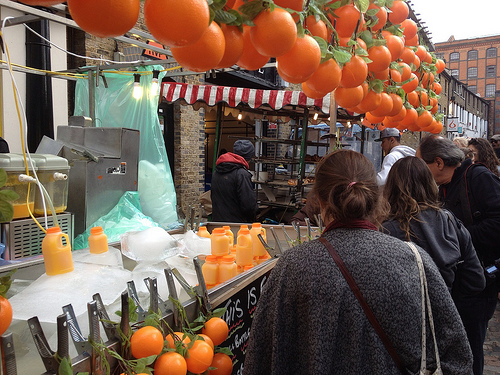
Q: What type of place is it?
A: It is a shopping center.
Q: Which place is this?
A: It is a shopping center.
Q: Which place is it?
A: It is a shopping center.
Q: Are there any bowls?
A: No, there are no bowls.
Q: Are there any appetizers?
A: No, there are no appetizers.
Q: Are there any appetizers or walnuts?
A: No, there are no appetizers or walnuts.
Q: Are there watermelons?
A: No, there are no watermelons.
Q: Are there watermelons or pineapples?
A: No, there are no watermelons or pineapples.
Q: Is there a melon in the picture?
A: No, there are no melons.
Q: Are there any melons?
A: No, there are no melons.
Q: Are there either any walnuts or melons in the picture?
A: No, there are no melons or walnuts.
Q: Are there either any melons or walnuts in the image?
A: No, there are no melons or walnuts.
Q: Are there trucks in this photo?
A: Yes, there is a truck.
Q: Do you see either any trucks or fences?
A: Yes, there is a truck.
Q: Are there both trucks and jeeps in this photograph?
A: No, there is a truck but no jeeps.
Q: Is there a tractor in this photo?
A: No, there are no tractors.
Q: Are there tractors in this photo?
A: No, there are no tractors.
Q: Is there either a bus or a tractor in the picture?
A: No, there are no tractors or buses.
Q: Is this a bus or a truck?
A: This is a truck.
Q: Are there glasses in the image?
A: No, there are no glasses.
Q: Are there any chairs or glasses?
A: No, there are no glasses or chairs.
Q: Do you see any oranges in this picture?
A: Yes, there are oranges.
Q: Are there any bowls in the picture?
A: No, there are no bowls.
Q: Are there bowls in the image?
A: No, there are no bowls.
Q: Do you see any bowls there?
A: No, there are no bowls.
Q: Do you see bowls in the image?
A: No, there are no bowls.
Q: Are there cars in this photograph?
A: No, there are no cars.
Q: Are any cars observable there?
A: No, there are no cars.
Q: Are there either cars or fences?
A: No, there are no cars or fences.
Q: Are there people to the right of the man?
A: Yes, there are people to the right of the man.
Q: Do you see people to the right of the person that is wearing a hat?
A: Yes, there are people to the right of the man.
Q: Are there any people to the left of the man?
A: No, the people are to the right of the man.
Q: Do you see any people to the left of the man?
A: No, the people are to the right of the man.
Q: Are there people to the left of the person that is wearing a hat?
A: No, the people are to the right of the man.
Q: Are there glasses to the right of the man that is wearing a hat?
A: No, there are people to the right of the man.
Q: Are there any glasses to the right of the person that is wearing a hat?
A: No, there are people to the right of the man.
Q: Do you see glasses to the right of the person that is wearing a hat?
A: No, there are people to the right of the man.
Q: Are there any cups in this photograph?
A: No, there are no cups.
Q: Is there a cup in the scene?
A: No, there are no cups.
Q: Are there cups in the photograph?
A: No, there are no cups.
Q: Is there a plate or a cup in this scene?
A: No, there are no cups or plates.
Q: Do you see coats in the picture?
A: Yes, there is a coat.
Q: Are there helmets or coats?
A: Yes, there is a coat.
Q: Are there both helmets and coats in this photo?
A: No, there is a coat but no helmets.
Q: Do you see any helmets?
A: No, there are no helmets.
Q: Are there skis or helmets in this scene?
A: No, there are no helmets or skis.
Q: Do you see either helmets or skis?
A: No, there are no helmets or skis.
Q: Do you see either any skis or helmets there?
A: No, there are no helmets or skis.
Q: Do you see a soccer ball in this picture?
A: No, there are no soccer balls.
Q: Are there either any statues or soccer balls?
A: No, there are no soccer balls or statues.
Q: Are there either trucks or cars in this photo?
A: Yes, there is a truck.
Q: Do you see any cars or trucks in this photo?
A: Yes, there is a truck.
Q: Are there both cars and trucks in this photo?
A: No, there is a truck but no cars.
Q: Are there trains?
A: No, there are no trains.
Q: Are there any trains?
A: No, there are no trains.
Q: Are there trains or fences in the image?
A: No, there are no trains or fences.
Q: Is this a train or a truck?
A: This is a truck.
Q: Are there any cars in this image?
A: No, there are no cars.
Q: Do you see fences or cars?
A: No, there are no cars or fences.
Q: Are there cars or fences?
A: No, there are no cars or fences.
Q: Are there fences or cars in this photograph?
A: No, there are no cars or fences.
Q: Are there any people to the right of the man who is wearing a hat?
A: Yes, there are people to the right of the man.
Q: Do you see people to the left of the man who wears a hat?
A: No, the people are to the right of the man.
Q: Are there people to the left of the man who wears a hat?
A: No, the people are to the right of the man.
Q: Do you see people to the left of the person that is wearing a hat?
A: No, the people are to the right of the man.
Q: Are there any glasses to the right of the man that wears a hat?
A: No, there are people to the right of the man.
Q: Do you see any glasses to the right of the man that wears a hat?
A: No, there are people to the right of the man.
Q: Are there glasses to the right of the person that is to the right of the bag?
A: No, there are people to the right of the man.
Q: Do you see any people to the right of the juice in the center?
A: Yes, there are people to the right of the juice.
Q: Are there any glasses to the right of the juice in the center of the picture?
A: No, there are people to the right of the juice.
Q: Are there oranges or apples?
A: Yes, there are oranges.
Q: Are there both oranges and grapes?
A: No, there are oranges but no grapes.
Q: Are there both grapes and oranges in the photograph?
A: No, there are oranges but no grapes.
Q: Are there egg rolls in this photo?
A: No, there are no egg rolls.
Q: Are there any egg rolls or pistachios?
A: No, there are no egg rolls or pistachios.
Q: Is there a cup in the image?
A: No, there are no cups.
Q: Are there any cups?
A: No, there are no cups.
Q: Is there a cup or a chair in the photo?
A: No, there are no cups or chairs.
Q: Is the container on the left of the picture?
A: Yes, the container is on the left of the image.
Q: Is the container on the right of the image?
A: No, the container is on the left of the image.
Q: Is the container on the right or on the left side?
A: The container is on the left of the image.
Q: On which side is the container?
A: The container is on the left of the image.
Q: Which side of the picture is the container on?
A: The container is on the left of the image.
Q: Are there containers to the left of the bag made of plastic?
A: Yes, there is a container to the left of the bag.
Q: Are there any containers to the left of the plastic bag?
A: Yes, there is a container to the left of the bag.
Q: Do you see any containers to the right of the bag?
A: No, the container is to the left of the bag.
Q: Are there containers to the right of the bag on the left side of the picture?
A: No, the container is to the left of the bag.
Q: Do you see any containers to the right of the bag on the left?
A: No, the container is to the left of the bag.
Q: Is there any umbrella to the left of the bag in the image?
A: No, there is a container to the left of the bag.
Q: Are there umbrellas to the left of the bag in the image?
A: No, there is a container to the left of the bag.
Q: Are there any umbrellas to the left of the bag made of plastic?
A: No, there is a container to the left of the bag.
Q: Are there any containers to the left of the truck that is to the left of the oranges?
A: Yes, there is a container to the left of the truck.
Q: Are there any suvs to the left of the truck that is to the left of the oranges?
A: No, there is a container to the left of the truck.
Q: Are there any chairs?
A: No, there are no chairs.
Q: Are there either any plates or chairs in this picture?
A: No, there are no chairs or plates.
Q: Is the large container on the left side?
A: Yes, the container is on the left of the image.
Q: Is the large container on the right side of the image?
A: No, the container is on the left of the image.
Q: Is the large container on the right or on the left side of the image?
A: The container is on the left of the image.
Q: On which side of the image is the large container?
A: The container is on the left of the image.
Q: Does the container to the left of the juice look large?
A: Yes, the container is large.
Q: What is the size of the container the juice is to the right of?
A: The container is large.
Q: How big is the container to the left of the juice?
A: The container is large.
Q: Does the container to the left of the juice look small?
A: No, the container is large.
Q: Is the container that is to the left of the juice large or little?
A: The container is large.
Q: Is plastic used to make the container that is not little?
A: Yes, the container is made of plastic.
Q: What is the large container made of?
A: The container is made of plastic.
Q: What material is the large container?
A: The container is made of plastic.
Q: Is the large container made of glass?
A: No, the container is made of plastic.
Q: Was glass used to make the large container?
A: No, the container is made of plastic.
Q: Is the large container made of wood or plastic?
A: The container is made of plastic.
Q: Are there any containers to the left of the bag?
A: Yes, there is a container to the left of the bag.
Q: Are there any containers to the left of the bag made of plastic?
A: Yes, there is a container to the left of the bag.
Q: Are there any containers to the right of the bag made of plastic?
A: No, the container is to the left of the bag.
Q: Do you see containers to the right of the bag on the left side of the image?
A: No, the container is to the left of the bag.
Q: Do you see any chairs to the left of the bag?
A: No, there is a container to the left of the bag.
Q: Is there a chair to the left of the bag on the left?
A: No, there is a container to the left of the bag.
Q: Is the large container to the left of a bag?
A: Yes, the container is to the left of a bag.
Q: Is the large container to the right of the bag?
A: No, the container is to the left of the bag.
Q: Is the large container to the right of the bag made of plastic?
A: No, the container is to the left of the bag.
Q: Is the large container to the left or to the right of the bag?
A: The container is to the left of the bag.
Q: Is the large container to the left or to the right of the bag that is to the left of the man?
A: The container is to the left of the bag.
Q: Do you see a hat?
A: Yes, there is a hat.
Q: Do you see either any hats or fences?
A: Yes, there is a hat.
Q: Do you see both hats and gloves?
A: No, there is a hat but no gloves.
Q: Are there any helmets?
A: No, there are no helmets.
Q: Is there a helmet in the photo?
A: No, there are no helmets.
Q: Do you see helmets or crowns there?
A: No, there are no helmets or crowns.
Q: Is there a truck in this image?
A: Yes, there is a truck.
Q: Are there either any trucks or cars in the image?
A: Yes, there is a truck.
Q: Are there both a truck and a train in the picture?
A: No, there is a truck but no trains.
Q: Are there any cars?
A: No, there are no cars.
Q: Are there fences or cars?
A: No, there are no cars or fences.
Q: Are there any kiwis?
A: No, there are no kiwis.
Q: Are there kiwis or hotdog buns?
A: No, there are no kiwis or hotdog buns.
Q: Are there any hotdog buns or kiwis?
A: No, there are no kiwis or hotdog buns.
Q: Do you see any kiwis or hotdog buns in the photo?
A: No, there are no kiwis or hotdog buns.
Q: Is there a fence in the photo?
A: No, there are no fences.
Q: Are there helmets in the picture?
A: No, there are no helmets.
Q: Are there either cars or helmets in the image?
A: No, there are no helmets or cars.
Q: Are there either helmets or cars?
A: No, there are no helmets or cars.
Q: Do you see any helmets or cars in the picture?
A: No, there are no helmets or cars.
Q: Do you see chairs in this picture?
A: No, there are no chairs.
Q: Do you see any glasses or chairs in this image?
A: No, there are no chairs or glasses.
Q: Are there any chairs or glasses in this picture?
A: No, there are no chairs or glasses.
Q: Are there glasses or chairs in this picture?
A: No, there are no chairs or glasses.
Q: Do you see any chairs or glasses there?
A: No, there are no chairs or glasses.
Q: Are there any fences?
A: No, there are no fences.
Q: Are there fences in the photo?
A: No, there are no fences.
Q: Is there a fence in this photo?
A: No, there are no fences.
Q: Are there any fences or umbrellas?
A: No, there are no fences or umbrellas.